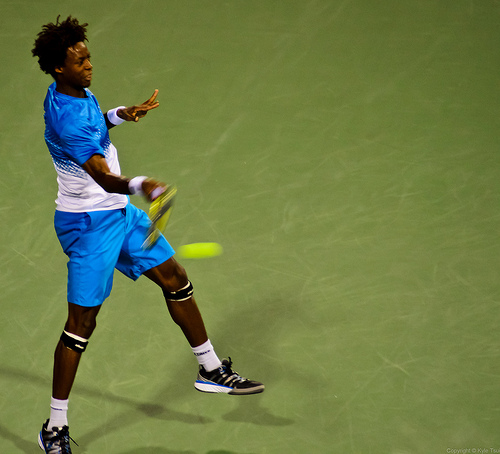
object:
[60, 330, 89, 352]
band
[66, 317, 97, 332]
knee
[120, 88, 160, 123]
hand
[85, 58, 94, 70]
nose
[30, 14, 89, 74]
hair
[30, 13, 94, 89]
head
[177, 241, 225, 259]
ball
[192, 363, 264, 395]
foot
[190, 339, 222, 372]
sock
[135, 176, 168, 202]
hand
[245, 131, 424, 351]
surface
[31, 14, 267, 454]
man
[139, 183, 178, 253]
bat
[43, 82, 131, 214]
shirt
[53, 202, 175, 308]
drawers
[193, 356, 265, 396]
shoe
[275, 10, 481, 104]
court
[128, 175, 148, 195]
band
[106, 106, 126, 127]
band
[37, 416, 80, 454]
sneakers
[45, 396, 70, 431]
sock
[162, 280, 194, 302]
band